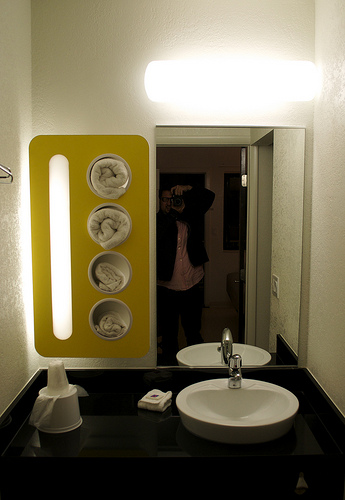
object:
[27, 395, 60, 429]
tissue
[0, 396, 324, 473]
counter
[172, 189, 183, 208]
camera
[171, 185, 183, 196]
hands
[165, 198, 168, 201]
lens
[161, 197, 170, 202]
eyeglasses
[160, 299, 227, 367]
ground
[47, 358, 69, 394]
cup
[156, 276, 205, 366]
pants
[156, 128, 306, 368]
mirror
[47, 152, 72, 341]
lamp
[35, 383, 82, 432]
dispenser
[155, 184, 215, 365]
reflection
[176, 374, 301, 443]
sink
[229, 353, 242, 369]
tap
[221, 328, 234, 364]
reflection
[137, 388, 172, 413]
towel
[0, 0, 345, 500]
bathroom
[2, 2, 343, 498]
picture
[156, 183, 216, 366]
man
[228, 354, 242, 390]
faucet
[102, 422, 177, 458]
reflection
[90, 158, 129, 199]
towel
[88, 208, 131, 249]
towel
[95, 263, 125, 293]
towel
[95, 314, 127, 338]
towel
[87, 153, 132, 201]
hole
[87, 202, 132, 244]
hole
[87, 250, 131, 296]
hole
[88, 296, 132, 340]
hole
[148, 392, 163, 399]
soap